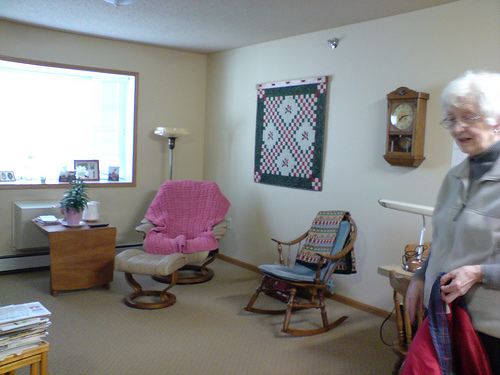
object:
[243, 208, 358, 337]
chair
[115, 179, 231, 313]
chair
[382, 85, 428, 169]
clock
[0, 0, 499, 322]
wall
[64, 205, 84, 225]
vase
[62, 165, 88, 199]
flowers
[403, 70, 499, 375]
lady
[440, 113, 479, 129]
spectacles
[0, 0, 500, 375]
room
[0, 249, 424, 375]
floor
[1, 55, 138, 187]
window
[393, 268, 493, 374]
jacket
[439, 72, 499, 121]
hair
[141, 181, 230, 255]
blanket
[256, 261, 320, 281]
cushion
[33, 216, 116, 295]
table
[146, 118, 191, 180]
lamp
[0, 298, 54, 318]
papers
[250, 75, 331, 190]
painting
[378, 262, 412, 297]
desk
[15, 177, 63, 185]
windowsill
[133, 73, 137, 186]
frame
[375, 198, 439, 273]
lamp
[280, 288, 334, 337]
chair leg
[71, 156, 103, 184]
picture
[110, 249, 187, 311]
ottoman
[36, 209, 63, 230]
mail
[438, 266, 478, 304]
hand